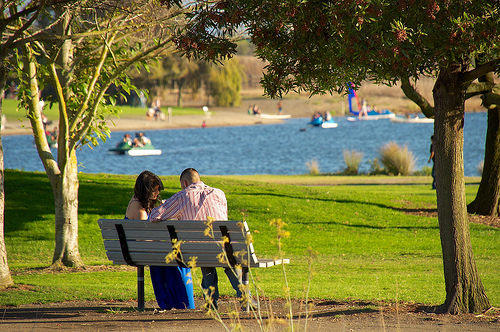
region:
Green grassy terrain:
[282, 187, 439, 308]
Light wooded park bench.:
[93, 216, 294, 315]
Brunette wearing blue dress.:
[127, 168, 192, 318]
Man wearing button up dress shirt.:
[161, 164, 251, 305]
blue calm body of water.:
[187, 128, 434, 168]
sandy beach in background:
[32, 102, 310, 135]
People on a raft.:
[104, 125, 179, 163]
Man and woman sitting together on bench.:
[104, 155, 280, 308]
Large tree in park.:
[12, 0, 159, 271]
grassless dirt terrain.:
[92, 305, 421, 330]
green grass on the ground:
[326, 204, 373, 235]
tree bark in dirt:
[429, 96, 489, 314]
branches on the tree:
[257, 9, 494, 79]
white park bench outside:
[92, 217, 289, 273]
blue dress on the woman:
[128, 208, 188, 307]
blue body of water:
[210, 136, 282, 166]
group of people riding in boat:
[118, 133, 160, 156]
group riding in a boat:
[309, 108, 341, 133]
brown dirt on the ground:
[401, 307, 469, 330]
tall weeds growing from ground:
[272, 218, 305, 330]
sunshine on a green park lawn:
[311, 232, 436, 287]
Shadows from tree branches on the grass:
[302, 188, 421, 243]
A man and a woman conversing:
[117, 165, 232, 216]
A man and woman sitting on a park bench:
[98, 163, 293, 312]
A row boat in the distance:
[107, 126, 167, 163]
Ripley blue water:
[222, 139, 302, 165]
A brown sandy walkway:
[320, 293, 450, 328]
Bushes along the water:
[304, 138, 422, 184]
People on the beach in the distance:
[138, 95, 298, 131]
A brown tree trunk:
[422, 94, 488, 329]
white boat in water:
[114, 119, 171, 164]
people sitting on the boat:
[121, 129, 151, 142]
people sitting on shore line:
[241, 94, 273, 129]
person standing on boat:
[356, 96, 376, 120]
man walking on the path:
[427, 132, 440, 185]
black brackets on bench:
[206, 223, 243, 271]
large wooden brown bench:
[93, 208, 292, 281]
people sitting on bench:
[127, 159, 232, 260]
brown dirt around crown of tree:
[36, 253, 103, 275]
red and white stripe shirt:
[181, 191, 223, 215]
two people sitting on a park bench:
[103, 158, 255, 301]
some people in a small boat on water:
[111, 127, 163, 159]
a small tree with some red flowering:
[246, 6, 489, 324]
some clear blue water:
[216, 131, 299, 163]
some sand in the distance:
[107, 115, 244, 129]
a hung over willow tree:
[172, 51, 242, 103]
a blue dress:
[151, 262, 192, 310]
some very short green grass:
[305, 213, 383, 250]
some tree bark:
[443, 160, 465, 295]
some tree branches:
[18, 5, 181, 43]